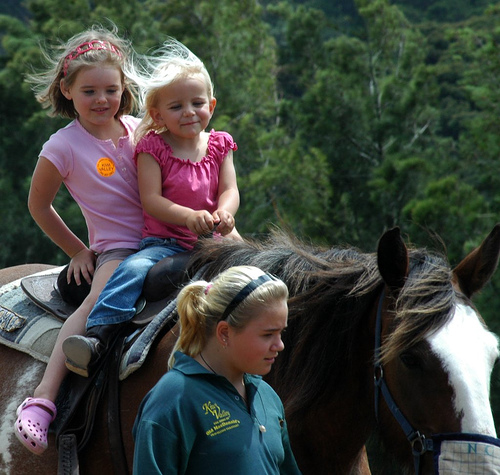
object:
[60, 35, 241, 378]
girl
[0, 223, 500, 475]
horse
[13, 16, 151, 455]
girl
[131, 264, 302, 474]
woman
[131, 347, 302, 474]
shirt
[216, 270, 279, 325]
headband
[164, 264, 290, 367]
hair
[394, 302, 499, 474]
face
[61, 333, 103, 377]
shoes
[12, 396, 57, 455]
shoes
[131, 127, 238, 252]
shirt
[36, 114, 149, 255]
shirt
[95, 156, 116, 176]
sticker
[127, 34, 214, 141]
hair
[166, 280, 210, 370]
ponytail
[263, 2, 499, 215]
trees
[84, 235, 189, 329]
jeans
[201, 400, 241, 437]
writing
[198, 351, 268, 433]
necklace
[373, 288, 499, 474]
harness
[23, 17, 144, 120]
hair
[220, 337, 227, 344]
earring